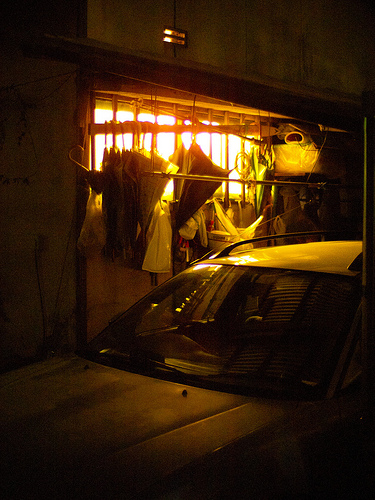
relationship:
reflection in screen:
[188, 267, 228, 299] [76, 263, 359, 400]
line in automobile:
[122, 53, 250, 122] [0, 223, 375, 500]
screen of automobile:
[76, 263, 359, 400] [0, 223, 375, 500]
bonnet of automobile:
[219, 232, 371, 356] [0, 223, 375, 500]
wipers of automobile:
[201, 324, 304, 386] [0, 223, 375, 500]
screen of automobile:
[167, 278, 321, 374] [0, 223, 375, 500]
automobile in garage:
[72, 308, 343, 462] [39, 56, 343, 369]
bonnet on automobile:
[0, 347, 313, 499] [72, 308, 343, 462]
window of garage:
[128, 89, 330, 247] [39, 56, 343, 369]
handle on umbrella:
[174, 100, 237, 151] [135, 147, 205, 259]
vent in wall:
[28, 15, 84, 38] [27, 59, 72, 138]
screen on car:
[76, 263, 359, 400] [49, 201, 364, 471]